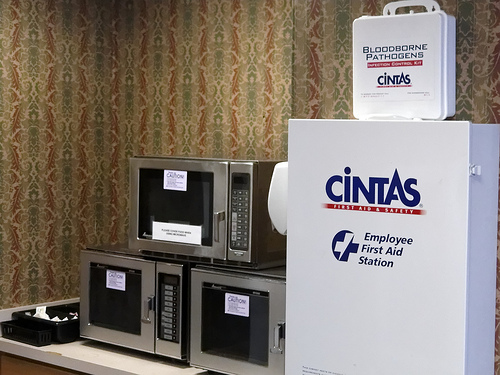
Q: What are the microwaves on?
A: Counter.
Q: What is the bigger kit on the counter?
A: First aid.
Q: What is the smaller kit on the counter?
A: Bloodborne pathogens.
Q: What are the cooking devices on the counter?
A: Microwave.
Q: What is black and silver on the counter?
A: Microwaves.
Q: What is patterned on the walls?
A: Wall paper.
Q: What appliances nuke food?
A: Microwaves.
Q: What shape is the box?
A: Square.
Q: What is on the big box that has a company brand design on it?
A: Logo.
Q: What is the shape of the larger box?
A: Rectangle.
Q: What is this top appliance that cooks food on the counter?
A: Microwave.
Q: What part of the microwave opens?
A: Door.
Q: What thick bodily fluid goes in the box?
A: Blood.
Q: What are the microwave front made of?
A: Metal.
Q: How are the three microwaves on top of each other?
A: Stacked.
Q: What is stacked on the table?
A: Microwaves.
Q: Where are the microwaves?
A: On the table.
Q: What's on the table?
A: Microwaves.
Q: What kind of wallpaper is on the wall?
A: Decorative.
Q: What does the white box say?
A: Cintas.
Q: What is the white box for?
A: First aid.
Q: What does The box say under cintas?
A: Employee first aid section.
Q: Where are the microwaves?
A: Next to the first aid kits.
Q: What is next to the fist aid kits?
A: The microwaves.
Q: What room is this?
A: Breakroom.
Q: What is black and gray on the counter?
A: Microwave.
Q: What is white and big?
A: Box.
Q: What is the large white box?
A: An employee first aid station.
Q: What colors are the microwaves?
A: Silver and black.